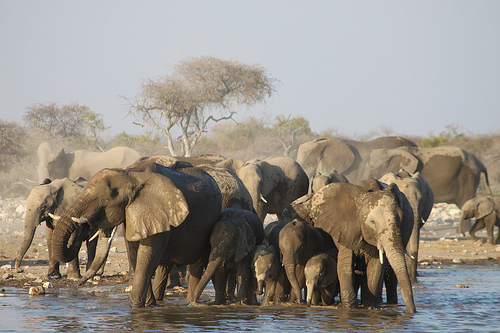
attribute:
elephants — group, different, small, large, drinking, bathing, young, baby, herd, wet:
[62, 162, 446, 309]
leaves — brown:
[157, 95, 180, 106]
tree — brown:
[143, 113, 232, 155]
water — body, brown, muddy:
[105, 303, 291, 322]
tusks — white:
[45, 210, 103, 229]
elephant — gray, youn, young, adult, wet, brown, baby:
[61, 186, 199, 304]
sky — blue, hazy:
[362, 54, 405, 80]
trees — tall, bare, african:
[17, 67, 350, 151]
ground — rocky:
[433, 247, 488, 268]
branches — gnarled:
[124, 113, 168, 132]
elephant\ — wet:
[55, 189, 212, 234]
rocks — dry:
[1, 272, 55, 289]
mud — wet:
[224, 296, 335, 325]